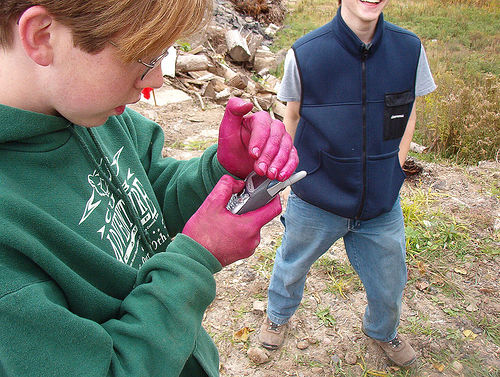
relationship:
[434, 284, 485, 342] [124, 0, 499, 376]
brown leaves on ground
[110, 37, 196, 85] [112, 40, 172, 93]
glasses on face